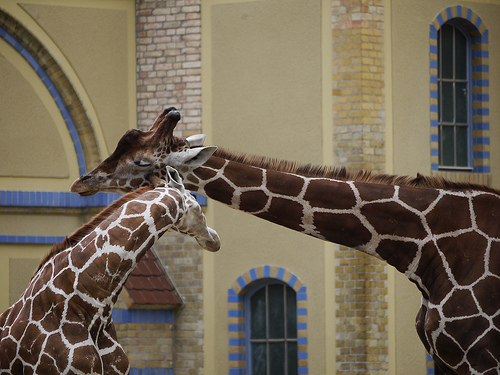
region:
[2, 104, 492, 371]
two giraffes in front of a building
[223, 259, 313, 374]
a window on the building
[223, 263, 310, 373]
blue and yellow trim around the window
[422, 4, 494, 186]
a blue and yellow trim around the window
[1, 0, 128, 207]
an arch in the window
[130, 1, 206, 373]
a brick section of the wall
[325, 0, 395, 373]
the brick corner of the building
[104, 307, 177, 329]
blue bricks on the wall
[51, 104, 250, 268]
giraffes rubbing heads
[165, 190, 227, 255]
the giraffe's nose is white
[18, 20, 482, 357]
two giraffes in a zoo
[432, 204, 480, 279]
brown spots on a giraffe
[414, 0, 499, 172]
arched window with blue and gold stripes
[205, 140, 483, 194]
brown hair along giraffe's neck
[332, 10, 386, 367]
light colored brick on building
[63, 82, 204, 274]
one giraffe cleaing the other giraffe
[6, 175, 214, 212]
blue accents on building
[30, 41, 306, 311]
two giraffes in front of an ornate building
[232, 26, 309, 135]
partts of building painted solid off white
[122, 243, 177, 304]
red shingles on part of building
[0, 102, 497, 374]
two giraffes touching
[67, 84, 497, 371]
taller giraffe with brown spots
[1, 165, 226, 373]
smaller giraffe with brown spots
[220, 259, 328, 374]
window with blue and gray stone border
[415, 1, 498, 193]
another window with blue and gray stone border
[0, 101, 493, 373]
two giraffes possibly showing affection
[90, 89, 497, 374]
giraffe with long neck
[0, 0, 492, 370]
blue, gray, beige building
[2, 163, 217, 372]
giraffe not showing his face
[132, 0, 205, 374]
light and dark colored bricks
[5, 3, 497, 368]
the wall is yellow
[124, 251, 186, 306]
red tile on the wall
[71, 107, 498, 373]
the giraffe is brown and white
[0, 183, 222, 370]
white spots on the giraffe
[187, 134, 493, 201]
a soft mane on the giraffe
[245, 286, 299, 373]
bars on the window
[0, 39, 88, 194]
the arch is filled in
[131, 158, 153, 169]
the giraffe's eye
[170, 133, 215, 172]
the giraffe's ear is white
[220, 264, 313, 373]
blue trim around the window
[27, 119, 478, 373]
Two giraffes hitting eachother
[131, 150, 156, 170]
The giraffe's eye is closed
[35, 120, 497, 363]
The giraffes are swinging their necks at eachother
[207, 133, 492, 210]
A short brown mane on the giraffe's back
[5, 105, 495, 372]
The giraffes are yellow and brown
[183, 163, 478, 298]
Large brown spots on the giraffe's body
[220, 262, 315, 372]
A blue and yellow frame around the window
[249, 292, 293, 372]
A paned glass window on the building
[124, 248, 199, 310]
Red shingles on the building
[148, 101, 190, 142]
very short horns on the giraffe's head